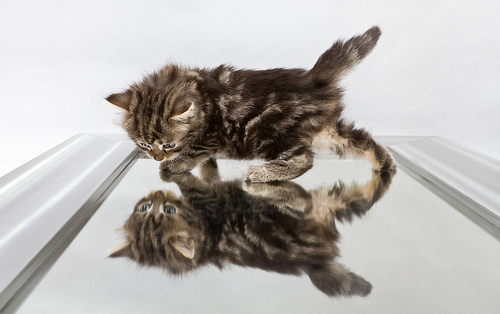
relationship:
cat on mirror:
[106, 26, 400, 175] [4, 144, 499, 313]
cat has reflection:
[106, 26, 400, 175] [115, 170, 401, 293]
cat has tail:
[106, 26, 400, 175] [310, 25, 383, 84]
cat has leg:
[106, 26, 400, 175] [248, 131, 316, 188]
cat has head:
[106, 26, 400, 175] [108, 83, 201, 160]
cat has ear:
[106, 26, 400, 175] [165, 97, 205, 134]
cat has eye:
[106, 26, 400, 175] [162, 138, 183, 153]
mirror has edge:
[4, 144, 499, 313] [399, 126, 500, 227]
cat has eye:
[106, 26, 400, 175] [138, 140, 158, 153]